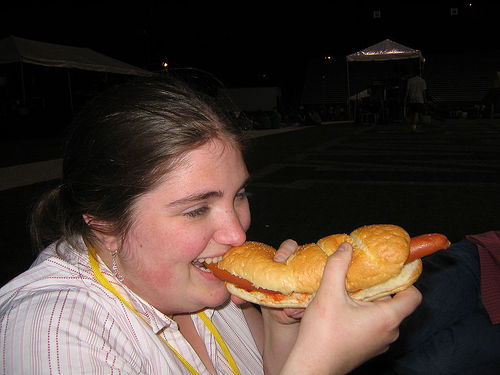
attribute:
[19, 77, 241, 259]
hair — brown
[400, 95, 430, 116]
shorts — black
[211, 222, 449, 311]
hotdog — long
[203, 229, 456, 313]
hotdog — footlong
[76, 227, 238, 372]
lanyard — yellow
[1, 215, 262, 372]
shirts — white, striped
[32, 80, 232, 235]
hair — brown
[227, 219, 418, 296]
bun — big